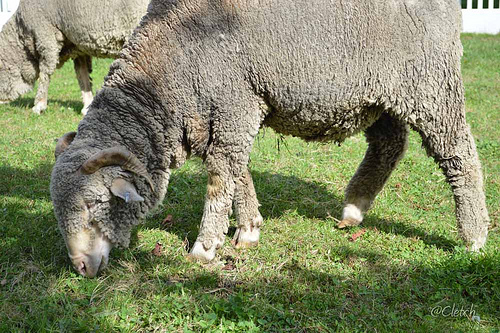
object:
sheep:
[48, 0, 491, 280]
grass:
[0, 93, 75, 172]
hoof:
[188, 231, 229, 262]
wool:
[97, 0, 462, 136]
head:
[47, 127, 170, 279]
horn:
[77, 146, 154, 191]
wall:
[458, 0, 500, 33]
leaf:
[151, 242, 163, 257]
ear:
[109, 178, 145, 203]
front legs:
[188, 93, 271, 219]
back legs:
[344, 84, 489, 194]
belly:
[268, 94, 378, 145]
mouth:
[95, 255, 105, 277]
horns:
[54, 131, 157, 192]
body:
[134, 0, 470, 146]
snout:
[67, 254, 88, 280]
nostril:
[80, 261, 87, 272]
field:
[0, 187, 499, 332]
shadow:
[0, 161, 454, 323]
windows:
[460, 0, 498, 10]